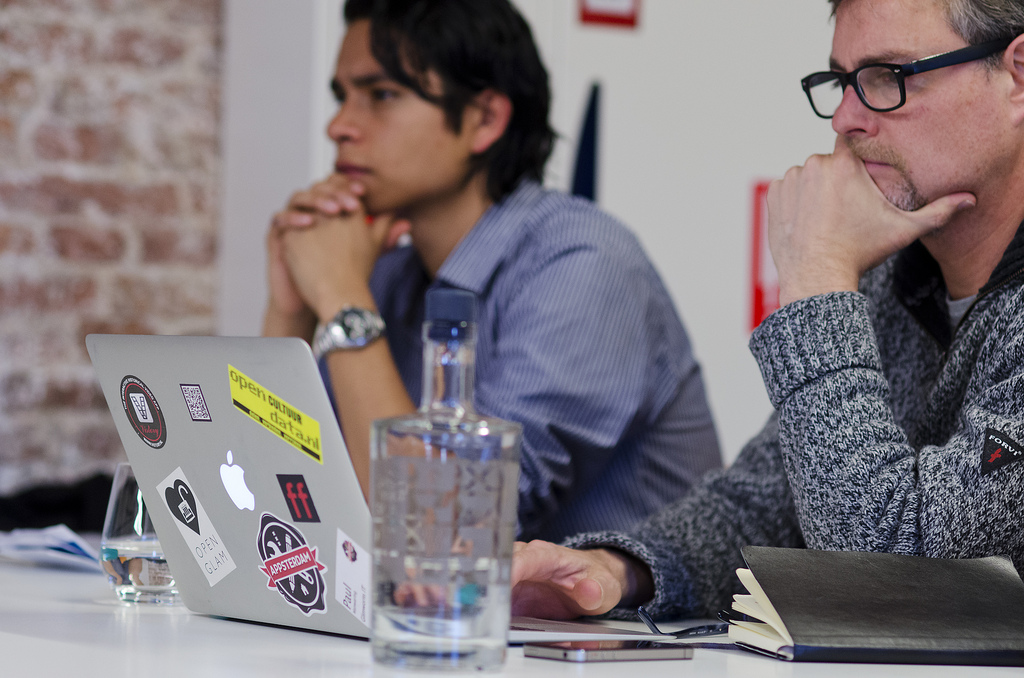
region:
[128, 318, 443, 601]
this is a computer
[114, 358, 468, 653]
the computer is a mac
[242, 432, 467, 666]
the computer is silver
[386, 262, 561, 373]
the bottle cap is blue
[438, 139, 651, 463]
the shirt is blue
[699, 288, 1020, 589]
the sweater is speckled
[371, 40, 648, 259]
the man's hair is long and black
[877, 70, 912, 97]
eye of the person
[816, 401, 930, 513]
arm of the person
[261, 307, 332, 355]
arm of the person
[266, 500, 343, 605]
sticker on the laptop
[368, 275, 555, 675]
A glass bottle.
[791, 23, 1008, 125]
Black rimmed glasses.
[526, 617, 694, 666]
A iphone cell phone on the table.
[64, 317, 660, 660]
An apple macbook open and being used.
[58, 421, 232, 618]
A glass full of a clear liquid.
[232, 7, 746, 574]
A man wearing a watch.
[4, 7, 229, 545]
A distressed brick wall.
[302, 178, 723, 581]
A striped blue collared shirt.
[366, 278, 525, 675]
the water bottle sitting on the table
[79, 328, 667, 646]
the laptop sitting on the table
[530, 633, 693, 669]
the cellphone sitting on the table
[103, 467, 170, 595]
the glass sitting on the table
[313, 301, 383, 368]
the watch on the man's wrist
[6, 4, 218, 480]
the brick wall next to the table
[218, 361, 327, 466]
the yellow sticker on the laptop lid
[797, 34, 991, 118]
the glasses on the man's face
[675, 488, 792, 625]
A person eating a orange.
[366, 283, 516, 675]
a bottle for holding liquid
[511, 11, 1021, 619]
a person is sitting down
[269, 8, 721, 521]
a person is sitting down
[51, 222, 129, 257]
a brick in a wall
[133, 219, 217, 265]
a brick in a wall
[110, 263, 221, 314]
a brick in a wall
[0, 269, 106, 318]
a brick in a wall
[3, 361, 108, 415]
a brick in a wall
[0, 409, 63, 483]
a brick in a wall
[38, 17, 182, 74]
a brick in a wall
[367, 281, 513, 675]
clear bottle with blue cap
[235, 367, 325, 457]
rectangular yellow sticker on laptop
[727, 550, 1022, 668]
black bound memo book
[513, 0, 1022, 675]
serious man wearing sweater and glasses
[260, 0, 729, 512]
young man wearing blue button down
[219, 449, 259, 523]
apple company logo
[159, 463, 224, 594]
sticker with a heart and padlock on it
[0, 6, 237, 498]
exposed brick wall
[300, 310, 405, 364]
large mens bracelet style watch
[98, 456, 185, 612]
glass stemless wine tumbler with water in it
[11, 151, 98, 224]
red brick ont he wall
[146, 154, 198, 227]
red brick ont he wall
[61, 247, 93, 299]
red brick ont he wall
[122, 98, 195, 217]
red brick ont he wall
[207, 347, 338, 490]
a sticker on the laptop